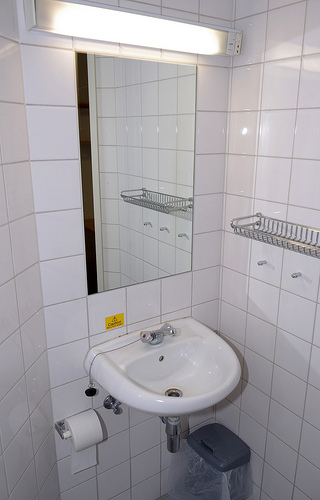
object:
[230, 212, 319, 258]
shelf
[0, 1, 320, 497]
wall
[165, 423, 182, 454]
pipe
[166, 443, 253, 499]
bag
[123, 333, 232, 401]
sink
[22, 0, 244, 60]
holder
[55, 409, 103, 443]
holder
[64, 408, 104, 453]
roll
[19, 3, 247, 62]
light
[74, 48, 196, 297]
mirror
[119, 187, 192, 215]
reflection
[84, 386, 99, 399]
plug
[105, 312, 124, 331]
sign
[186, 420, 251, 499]
garbage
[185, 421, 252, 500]
can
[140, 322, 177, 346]
faucet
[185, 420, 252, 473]
lid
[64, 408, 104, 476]
toilet paper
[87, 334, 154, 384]
chain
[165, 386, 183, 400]
drain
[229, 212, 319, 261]
rack